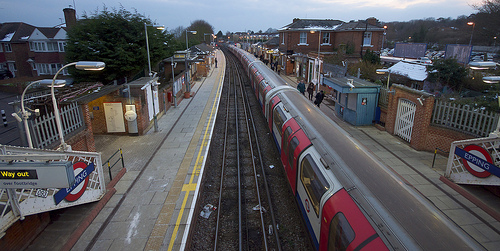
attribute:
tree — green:
[72, 12, 186, 93]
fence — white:
[428, 93, 498, 148]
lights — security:
[8, 38, 130, 208]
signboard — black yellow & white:
[0, 164, 42, 183]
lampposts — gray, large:
[16, 50, 130, 181]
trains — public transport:
[289, 124, 426, 221]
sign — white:
[444, 136, 499, 186]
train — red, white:
[218, 44, 498, 239]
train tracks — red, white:
[211, 71, 270, 247]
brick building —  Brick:
[1, 5, 73, 80]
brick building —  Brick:
[278, 15, 384, 67]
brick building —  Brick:
[74, 76, 184, 134]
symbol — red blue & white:
[35, 143, 113, 218]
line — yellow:
[166, 50, 225, 250]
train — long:
[223, 38, 485, 248]